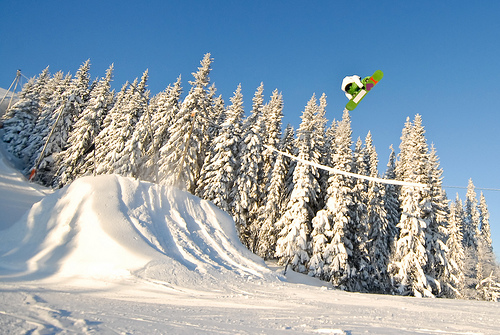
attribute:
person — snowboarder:
[340, 74, 367, 100]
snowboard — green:
[344, 68, 385, 112]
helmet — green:
[346, 84, 361, 95]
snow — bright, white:
[151, 160, 204, 184]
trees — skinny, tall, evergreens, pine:
[2, 51, 500, 306]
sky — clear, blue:
[0, 1, 499, 258]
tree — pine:
[275, 129, 312, 278]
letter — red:
[369, 77, 380, 85]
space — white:
[351, 88, 367, 105]